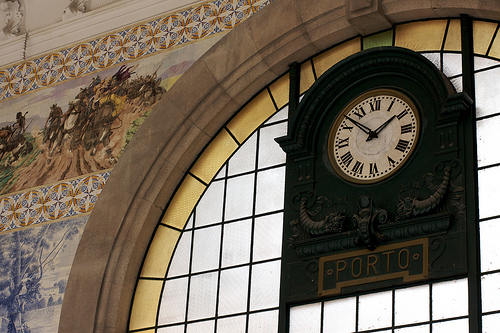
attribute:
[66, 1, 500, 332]
window — arch, glass, white, arched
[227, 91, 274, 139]
glass — yellow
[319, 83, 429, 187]
clock — 1:52, white, circular, shaped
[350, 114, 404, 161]
face — white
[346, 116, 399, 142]
hands — black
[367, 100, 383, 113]
numerals — roman, black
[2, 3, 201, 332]
wall — colorful, blue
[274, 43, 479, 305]
frame — green, decorative, black, metallic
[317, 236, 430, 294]
writings — bold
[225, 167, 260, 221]
glass — white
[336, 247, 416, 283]
porto — brown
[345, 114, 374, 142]
hand — black, minute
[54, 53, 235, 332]
frame — stone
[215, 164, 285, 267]
tiles — square